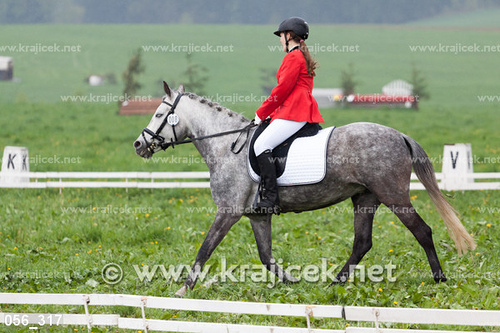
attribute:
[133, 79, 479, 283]
horse — gray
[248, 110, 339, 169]
pants — white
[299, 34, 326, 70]
hair — brown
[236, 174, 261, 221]
boots — black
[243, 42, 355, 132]
jacket — red